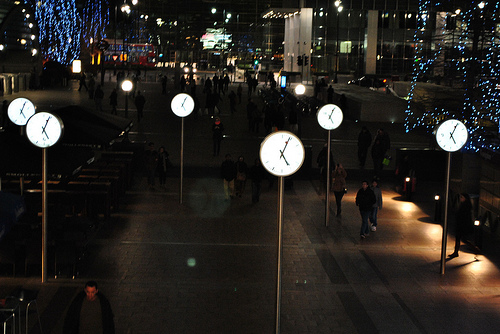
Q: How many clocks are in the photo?
A: Seven.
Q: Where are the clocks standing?
A: Sidewalk.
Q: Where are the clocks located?
A: City.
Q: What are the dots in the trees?
A: String lights.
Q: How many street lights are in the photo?
A: Two.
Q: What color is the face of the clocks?
A: Black and white.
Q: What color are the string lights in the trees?
A: Blue.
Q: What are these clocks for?
A: New Year's Eve.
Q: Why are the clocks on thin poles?
A: To hold them.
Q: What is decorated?
A: The street.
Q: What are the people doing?
A: Walking.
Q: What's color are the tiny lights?
A: Blur.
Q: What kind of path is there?
A: Brick.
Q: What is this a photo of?
A: People walking through city at night.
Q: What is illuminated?
A: Six tall decorative clocks.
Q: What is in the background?
A: City buildings lit up at night.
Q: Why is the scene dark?
A: It is nighttime.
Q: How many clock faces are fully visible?
A: Six.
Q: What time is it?
A: Ten minutes after five.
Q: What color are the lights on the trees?
A: Blue.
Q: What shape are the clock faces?
A: Round.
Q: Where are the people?
A: Walking on the streets and sidewalk.